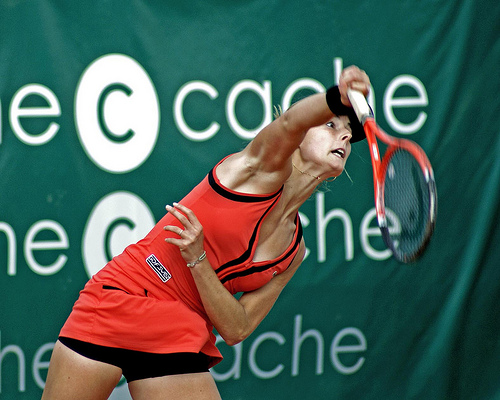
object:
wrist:
[186, 250, 210, 278]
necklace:
[293, 163, 324, 183]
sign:
[0, 3, 497, 400]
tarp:
[0, 0, 498, 398]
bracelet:
[186, 251, 207, 268]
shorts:
[53, 333, 213, 384]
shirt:
[57, 152, 304, 369]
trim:
[207, 167, 284, 203]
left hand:
[162, 202, 204, 264]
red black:
[59, 151, 304, 382]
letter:
[98, 81, 135, 143]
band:
[325, 85, 352, 116]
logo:
[145, 253, 173, 282]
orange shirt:
[56, 152, 304, 369]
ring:
[178, 230, 184, 236]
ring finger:
[163, 225, 184, 237]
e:
[8, 83, 61, 147]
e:
[381, 72, 430, 135]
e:
[22, 218, 69, 276]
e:
[357, 206, 402, 263]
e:
[330, 326, 368, 377]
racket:
[344, 84, 441, 265]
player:
[39, 64, 374, 400]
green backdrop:
[446, 0, 500, 400]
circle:
[72, 51, 161, 175]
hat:
[341, 109, 366, 145]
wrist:
[324, 84, 344, 124]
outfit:
[53, 151, 302, 385]